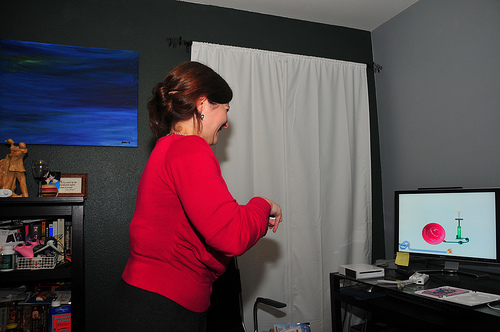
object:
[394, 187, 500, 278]
computer monitor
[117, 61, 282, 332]
lady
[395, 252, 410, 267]
note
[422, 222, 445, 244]
ball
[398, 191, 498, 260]
screen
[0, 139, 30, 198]
figurine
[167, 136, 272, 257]
sleeves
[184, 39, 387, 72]
curtain rod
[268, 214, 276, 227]
controller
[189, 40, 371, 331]
curtain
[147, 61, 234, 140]
hair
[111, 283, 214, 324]
bottom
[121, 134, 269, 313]
shirt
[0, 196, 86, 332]
book case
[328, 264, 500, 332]
desk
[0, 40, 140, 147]
painting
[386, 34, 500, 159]
wall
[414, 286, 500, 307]
book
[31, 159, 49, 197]
glass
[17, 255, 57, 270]
box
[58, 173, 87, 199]
frame